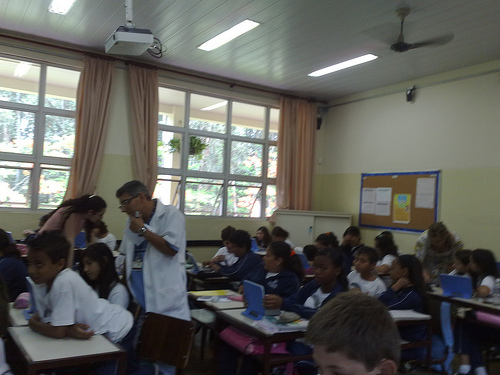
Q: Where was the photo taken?
A: It was taken at the classroom.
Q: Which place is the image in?
A: It is at the classroom.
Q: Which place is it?
A: It is a classroom.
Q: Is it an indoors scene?
A: Yes, it is indoors.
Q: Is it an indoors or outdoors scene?
A: It is indoors.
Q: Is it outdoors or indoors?
A: It is indoors.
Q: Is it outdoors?
A: No, it is indoors.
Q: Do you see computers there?
A: Yes, there is a computer.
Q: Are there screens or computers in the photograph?
A: Yes, there is a computer.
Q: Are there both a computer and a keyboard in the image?
A: No, there is a computer but no keyboards.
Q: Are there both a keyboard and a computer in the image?
A: No, there is a computer but no keyboards.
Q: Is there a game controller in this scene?
A: No, there are no game controllers.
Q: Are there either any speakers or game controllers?
A: No, there are no game controllers or speakers.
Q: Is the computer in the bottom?
A: Yes, the computer is in the bottom of the image.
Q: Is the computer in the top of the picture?
A: No, the computer is in the bottom of the image.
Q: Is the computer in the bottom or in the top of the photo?
A: The computer is in the bottom of the image.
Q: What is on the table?
A: The computer is on the table.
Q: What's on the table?
A: The computer is on the table.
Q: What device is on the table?
A: The device is a computer.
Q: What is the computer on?
A: The computer is on the table.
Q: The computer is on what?
A: The computer is on the table.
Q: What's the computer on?
A: The computer is on the table.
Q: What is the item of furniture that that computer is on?
A: The piece of furniture is a table.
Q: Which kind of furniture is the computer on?
A: The computer is on the table.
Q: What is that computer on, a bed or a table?
A: The computer is on a table.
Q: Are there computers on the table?
A: Yes, there is a computer on the table.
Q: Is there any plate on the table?
A: No, there is a computer on the table.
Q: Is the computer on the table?
A: Yes, the computer is on the table.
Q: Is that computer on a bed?
A: No, the computer is on the table.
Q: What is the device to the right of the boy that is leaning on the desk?
A: The device is a computer.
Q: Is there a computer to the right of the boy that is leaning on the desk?
A: Yes, there is a computer to the right of the boy.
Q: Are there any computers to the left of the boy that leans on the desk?
A: No, the computer is to the right of the boy.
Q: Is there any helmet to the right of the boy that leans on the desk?
A: No, there is a computer to the right of the boy.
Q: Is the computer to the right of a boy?
A: Yes, the computer is to the right of a boy.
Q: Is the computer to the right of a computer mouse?
A: No, the computer is to the right of a boy.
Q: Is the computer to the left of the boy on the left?
A: No, the computer is to the right of the boy.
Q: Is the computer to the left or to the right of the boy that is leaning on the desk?
A: The computer is to the right of the boy.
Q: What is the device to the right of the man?
A: The device is a computer.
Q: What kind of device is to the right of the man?
A: The device is a computer.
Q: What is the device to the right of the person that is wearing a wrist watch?
A: The device is a computer.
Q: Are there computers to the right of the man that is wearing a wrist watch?
A: Yes, there is a computer to the right of the man.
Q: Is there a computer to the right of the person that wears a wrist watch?
A: Yes, there is a computer to the right of the man.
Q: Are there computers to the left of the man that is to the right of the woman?
A: No, the computer is to the right of the man.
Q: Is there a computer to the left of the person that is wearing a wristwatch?
A: No, the computer is to the right of the man.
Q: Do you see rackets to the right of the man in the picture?
A: No, there is a computer to the right of the man.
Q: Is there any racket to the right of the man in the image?
A: No, there is a computer to the right of the man.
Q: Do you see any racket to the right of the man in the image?
A: No, there is a computer to the right of the man.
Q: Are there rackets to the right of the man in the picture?
A: No, there is a computer to the right of the man.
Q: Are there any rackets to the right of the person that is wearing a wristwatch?
A: No, there is a computer to the right of the man.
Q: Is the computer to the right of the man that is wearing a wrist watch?
A: Yes, the computer is to the right of the man.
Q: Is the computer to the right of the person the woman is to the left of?
A: Yes, the computer is to the right of the man.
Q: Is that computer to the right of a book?
A: No, the computer is to the right of the man.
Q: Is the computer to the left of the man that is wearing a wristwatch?
A: No, the computer is to the right of the man.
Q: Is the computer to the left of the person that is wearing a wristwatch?
A: No, the computer is to the right of the man.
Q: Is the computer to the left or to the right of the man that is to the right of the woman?
A: The computer is to the right of the man.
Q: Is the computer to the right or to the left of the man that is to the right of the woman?
A: The computer is to the right of the man.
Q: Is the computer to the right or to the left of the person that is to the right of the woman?
A: The computer is to the right of the man.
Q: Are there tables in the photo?
A: Yes, there is a table.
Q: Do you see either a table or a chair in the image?
A: Yes, there is a table.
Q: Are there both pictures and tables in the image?
A: No, there is a table but no pictures.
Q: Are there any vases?
A: No, there are no vases.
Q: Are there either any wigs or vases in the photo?
A: No, there are no vases or wigs.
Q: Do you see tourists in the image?
A: No, there are no tourists.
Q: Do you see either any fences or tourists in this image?
A: No, there are no tourists or fences.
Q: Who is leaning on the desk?
A: The boy is leaning on the desk.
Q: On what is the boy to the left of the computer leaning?
A: The boy is leaning on the desk.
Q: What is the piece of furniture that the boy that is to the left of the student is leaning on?
A: The piece of furniture is a desk.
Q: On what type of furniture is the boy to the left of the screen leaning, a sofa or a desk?
A: The boy is leaning on a desk.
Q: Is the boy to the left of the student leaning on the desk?
A: Yes, the boy is leaning on the desk.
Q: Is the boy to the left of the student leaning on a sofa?
A: No, the boy is leaning on the desk.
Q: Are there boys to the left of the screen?
A: Yes, there is a boy to the left of the screen.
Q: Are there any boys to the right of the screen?
A: No, the boy is to the left of the screen.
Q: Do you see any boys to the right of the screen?
A: No, the boy is to the left of the screen.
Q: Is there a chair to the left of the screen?
A: No, there is a boy to the left of the screen.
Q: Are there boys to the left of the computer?
A: Yes, there is a boy to the left of the computer.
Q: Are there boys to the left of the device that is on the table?
A: Yes, there is a boy to the left of the computer.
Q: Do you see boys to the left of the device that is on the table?
A: Yes, there is a boy to the left of the computer.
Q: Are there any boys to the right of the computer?
A: No, the boy is to the left of the computer.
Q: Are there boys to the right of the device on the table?
A: No, the boy is to the left of the computer.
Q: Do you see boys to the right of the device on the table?
A: No, the boy is to the left of the computer.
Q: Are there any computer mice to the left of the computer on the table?
A: No, there is a boy to the left of the computer.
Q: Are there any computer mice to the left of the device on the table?
A: No, there is a boy to the left of the computer.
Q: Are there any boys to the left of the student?
A: Yes, there is a boy to the left of the student.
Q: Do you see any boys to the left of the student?
A: Yes, there is a boy to the left of the student.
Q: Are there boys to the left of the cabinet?
A: Yes, there is a boy to the left of the cabinet.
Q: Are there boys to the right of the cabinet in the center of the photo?
A: No, the boy is to the left of the cabinet.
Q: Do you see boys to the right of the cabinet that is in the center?
A: No, the boy is to the left of the cabinet.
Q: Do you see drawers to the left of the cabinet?
A: No, there is a boy to the left of the cabinet.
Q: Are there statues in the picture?
A: No, there are no statues.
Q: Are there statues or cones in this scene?
A: No, there are no statues or cones.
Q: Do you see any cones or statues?
A: No, there are no statues or cones.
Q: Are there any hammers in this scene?
A: No, there are no hammers.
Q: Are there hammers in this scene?
A: No, there are no hammers.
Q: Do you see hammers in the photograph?
A: No, there are no hammers.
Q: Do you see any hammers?
A: No, there are no hammers.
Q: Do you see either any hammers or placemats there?
A: No, there are no hammers or placemats.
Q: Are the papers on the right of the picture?
A: Yes, the papers are on the right of the image.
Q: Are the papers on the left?
A: No, the papers are on the right of the image.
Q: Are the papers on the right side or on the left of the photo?
A: The papers are on the right of the image.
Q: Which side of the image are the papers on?
A: The papers are on the right of the image.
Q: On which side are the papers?
A: The papers are on the right of the image.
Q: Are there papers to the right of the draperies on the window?
A: Yes, there are papers to the right of the draperies.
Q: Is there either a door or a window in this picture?
A: Yes, there is a window.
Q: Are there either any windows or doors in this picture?
A: Yes, there is a window.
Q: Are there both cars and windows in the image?
A: No, there is a window but no cars.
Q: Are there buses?
A: No, there are no buses.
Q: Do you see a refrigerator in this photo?
A: No, there are no refrigerators.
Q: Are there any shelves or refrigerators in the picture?
A: No, there are no refrigerators or shelves.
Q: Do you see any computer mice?
A: No, there are no computer mice.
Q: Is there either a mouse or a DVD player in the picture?
A: No, there are no computer mice or DVD players.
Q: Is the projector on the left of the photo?
A: Yes, the projector is on the left of the image.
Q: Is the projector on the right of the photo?
A: No, the projector is on the left of the image.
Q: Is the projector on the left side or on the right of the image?
A: The projector is on the left of the image.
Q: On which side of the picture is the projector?
A: The projector is on the left of the image.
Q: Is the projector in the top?
A: Yes, the projector is in the top of the image.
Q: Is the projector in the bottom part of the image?
A: No, the projector is in the top of the image.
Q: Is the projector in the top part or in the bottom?
A: The projector is in the top of the image.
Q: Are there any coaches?
A: No, there are no coaches.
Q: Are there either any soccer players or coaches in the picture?
A: No, there are no coaches or soccer players.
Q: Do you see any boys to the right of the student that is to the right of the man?
A: Yes, there are boys to the right of the student.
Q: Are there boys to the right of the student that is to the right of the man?
A: Yes, there are boys to the right of the student.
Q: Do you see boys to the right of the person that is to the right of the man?
A: Yes, there are boys to the right of the student.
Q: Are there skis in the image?
A: No, there are no skis.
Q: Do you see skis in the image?
A: No, there are no skis.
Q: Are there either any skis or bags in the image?
A: No, there are no skis or bags.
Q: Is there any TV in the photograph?
A: No, there are no televisions.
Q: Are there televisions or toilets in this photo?
A: No, there are no televisions or toilets.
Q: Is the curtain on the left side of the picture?
A: Yes, the curtain is on the left of the image.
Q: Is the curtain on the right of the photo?
A: No, the curtain is on the left of the image.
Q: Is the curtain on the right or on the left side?
A: The curtain is on the left of the image.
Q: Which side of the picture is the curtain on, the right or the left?
A: The curtain is on the left of the image.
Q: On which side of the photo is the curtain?
A: The curtain is on the left of the image.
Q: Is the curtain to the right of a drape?
A: Yes, the curtain is to the right of a drape.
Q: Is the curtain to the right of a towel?
A: No, the curtain is to the right of a drape.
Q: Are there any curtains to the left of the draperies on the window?
A: Yes, there is a curtain to the left of the draperies.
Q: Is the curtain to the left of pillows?
A: No, the curtain is to the left of the drapes.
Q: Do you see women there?
A: Yes, there is a woman.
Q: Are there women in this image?
A: Yes, there is a woman.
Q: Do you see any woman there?
A: Yes, there is a woman.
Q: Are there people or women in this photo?
A: Yes, there is a woman.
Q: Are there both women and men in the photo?
A: Yes, there are both a woman and a man.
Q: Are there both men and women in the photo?
A: Yes, there are both a woman and a man.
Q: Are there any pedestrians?
A: No, there are no pedestrians.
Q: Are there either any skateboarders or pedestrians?
A: No, there are no pedestrians or skateboarders.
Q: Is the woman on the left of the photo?
A: Yes, the woman is on the left of the image.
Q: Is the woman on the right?
A: No, the woman is on the left of the image.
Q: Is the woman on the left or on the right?
A: The woman is on the left of the image.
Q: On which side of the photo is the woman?
A: The woman is on the left of the image.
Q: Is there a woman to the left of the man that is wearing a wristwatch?
A: Yes, there is a woman to the left of the man.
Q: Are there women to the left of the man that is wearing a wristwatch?
A: Yes, there is a woman to the left of the man.